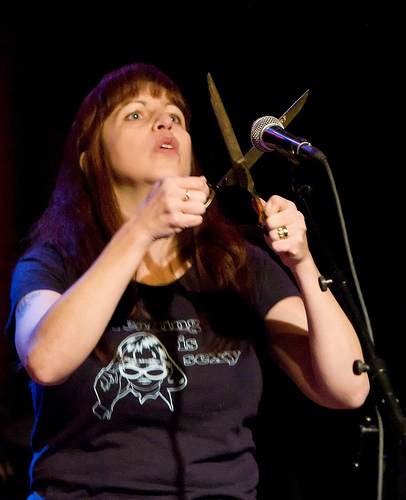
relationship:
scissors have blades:
[204, 72, 308, 237] [202, 71, 286, 167]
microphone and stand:
[251, 116, 325, 169] [322, 157, 404, 497]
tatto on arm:
[15, 287, 38, 338] [49, 171, 199, 384]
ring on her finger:
[275, 225, 287, 239] [266, 221, 305, 243]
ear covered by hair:
[78, 149, 88, 172] [70, 99, 102, 263]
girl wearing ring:
[5, 65, 368, 500] [274, 223, 291, 240]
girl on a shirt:
[93, 330, 187, 420] [36, 215, 338, 421]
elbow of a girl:
[301, 351, 371, 408] [5, 65, 368, 500]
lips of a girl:
[154, 134, 179, 156] [5, 65, 368, 500]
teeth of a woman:
[161, 143, 173, 148] [62, 54, 215, 234]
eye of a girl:
[126, 109, 142, 120] [5, 65, 368, 500]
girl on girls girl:
[93, 330, 187, 420] [2, 43, 401, 489]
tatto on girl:
[17, 290, 38, 318] [2, 43, 401, 489]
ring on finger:
[181, 184, 192, 201] [174, 186, 205, 199]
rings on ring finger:
[275, 225, 290, 237] [268, 224, 304, 241]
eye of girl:
[166, 111, 182, 124] [1, 56, 373, 498]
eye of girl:
[124, 110, 143, 121] [1, 56, 373, 498]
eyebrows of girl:
[112, 99, 146, 122] [1, 56, 373, 498]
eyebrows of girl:
[163, 102, 175, 106] [1, 56, 373, 498]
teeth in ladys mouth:
[161, 143, 173, 148] [152, 135, 179, 154]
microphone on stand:
[244, 114, 329, 181] [273, 170, 405, 498]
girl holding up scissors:
[5, 65, 368, 500] [196, 68, 317, 224]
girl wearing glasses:
[99, 338, 204, 453] [117, 359, 169, 381]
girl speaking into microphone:
[5, 65, 368, 500] [246, 115, 404, 497]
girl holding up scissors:
[5, 65, 368, 500] [190, 71, 311, 231]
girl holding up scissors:
[5, 65, 368, 500] [171, 68, 337, 259]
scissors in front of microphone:
[171, 68, 337, 259] [250, 115, 323, 167]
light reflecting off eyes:
[75, 71, 200, 235] [122, 106, 184, 124]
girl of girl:
[93, 330, 187, 420] [93, 330, 187, 420]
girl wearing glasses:
[93, 330, 187, 420] [116, 360, 167, 379]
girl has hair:
[5, 65, 368, 500] [26, 62, 247, 319]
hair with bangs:
[26, 62, 247, 319] [78, 62, 187, 112]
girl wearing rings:
[5, 65, 368, 500] [264, 198, 295, 247]